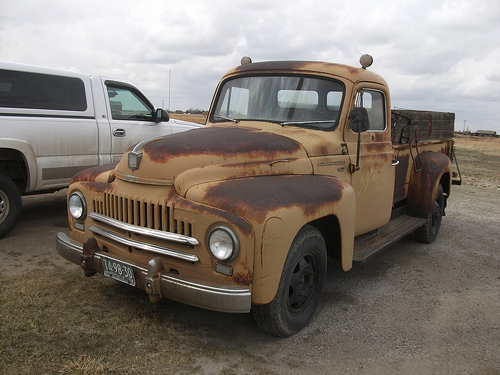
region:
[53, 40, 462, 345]
Rusty and brown truck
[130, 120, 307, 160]
Huge rust mark on the hood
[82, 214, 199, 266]
Chrome grill on the car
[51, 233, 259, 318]
Chrome front bumper on car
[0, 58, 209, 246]
White dirty vehicle next to truck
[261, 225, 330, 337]
Front black wheel of truck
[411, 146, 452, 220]
Rusted part over rear wheel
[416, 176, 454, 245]
Black rear wheel of truck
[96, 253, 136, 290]
Black and white license plate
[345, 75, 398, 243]
Driver side door of car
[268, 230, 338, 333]
a black rubber tire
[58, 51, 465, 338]
a rusty yellow old pickup truck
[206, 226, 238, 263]
a pair of white headlights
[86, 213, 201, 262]
a metal front grille to a truck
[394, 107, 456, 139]
a wooden bed to a pickup truck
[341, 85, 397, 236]
a yellow rusty truck door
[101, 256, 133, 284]
a black license plate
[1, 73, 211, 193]
a white pickup truck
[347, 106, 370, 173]
a black truck mirror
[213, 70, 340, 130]
a front windshield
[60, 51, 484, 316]
old tan truck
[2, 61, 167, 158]
white truck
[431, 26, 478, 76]
white clouds in blue sky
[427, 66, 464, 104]
white clouds in blue sky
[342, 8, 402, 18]
white clouds in blue sky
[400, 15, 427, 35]
white clouds in blue sky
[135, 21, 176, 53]
white clouds in blue sky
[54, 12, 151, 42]
white clouds in blue sky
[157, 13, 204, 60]
white clouds in blue sky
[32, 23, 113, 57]
white clouds in blue sky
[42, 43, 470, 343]
tan truck parked on dirt ground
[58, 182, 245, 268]
headlights on front of truck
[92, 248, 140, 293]
grey and white license plate on front of truck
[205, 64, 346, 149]
glass truck windowshield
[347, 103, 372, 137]
grey rear view window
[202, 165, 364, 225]
brown rust spot on truck quarter panel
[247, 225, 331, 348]
black tire on front of truck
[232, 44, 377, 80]
two lights on hood of truck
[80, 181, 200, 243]
black grill on front of truck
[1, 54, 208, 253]
white truck parked next to brown truck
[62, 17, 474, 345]
the car is brown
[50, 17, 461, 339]
the car is rusty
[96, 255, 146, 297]
license plate on front of car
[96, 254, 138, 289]
white numbers on the plate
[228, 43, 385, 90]
lights on top of car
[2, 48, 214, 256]
white car parked next to brown car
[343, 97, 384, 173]
car's side mirror is black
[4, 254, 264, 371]
brown grass under the car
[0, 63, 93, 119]
car window is black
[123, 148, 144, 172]
light on the hood